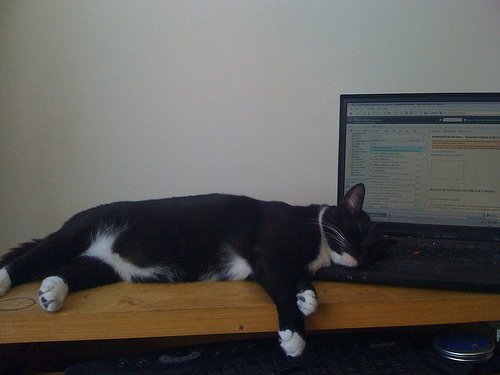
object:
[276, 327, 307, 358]
paw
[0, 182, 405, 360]
black/white cat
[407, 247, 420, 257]
button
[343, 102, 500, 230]
screen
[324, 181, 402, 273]
head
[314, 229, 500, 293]
keyboard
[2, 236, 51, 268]
tail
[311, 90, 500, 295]
laptop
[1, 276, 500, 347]
desk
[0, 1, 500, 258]
wall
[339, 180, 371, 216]
ear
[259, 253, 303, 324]
leg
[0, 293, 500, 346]
edge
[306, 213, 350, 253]
whiskers